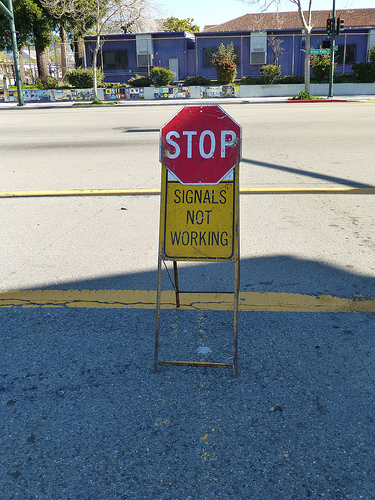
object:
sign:
[153, 105, 241, 374]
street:
[261, 159, 331, 271]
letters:
[170, 229, 227, 249]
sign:
[167, 89, 229, 171]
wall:
[98, 86, 246, 102]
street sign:
[304, 43, 347, 57]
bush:
[206, 43, 240, 82]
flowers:
[219, 59, 235, 70]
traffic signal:
[325, 17, 334, 36]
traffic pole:
[329, 55, 337, 99]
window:
[84, 49, 129, 72]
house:
[84, 30, 374, 87]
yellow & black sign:
[159, 180, 238, 262]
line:
[10, 189, 124, 202]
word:
[186, 207, 212, 228]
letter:
[163, 126, 193, 172]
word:
[170, 229, 228, 246]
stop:
[165, 127, 238, 161]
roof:
[243, 14, 300, 31]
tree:
[4, 0, 26, 106]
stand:
[141, 268, 255, 344]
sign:
[106, 177, 270, 261]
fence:
[110, 37, 169, 56]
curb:
[287, 96, 347, 106]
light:
[323, 9, 346, 37]